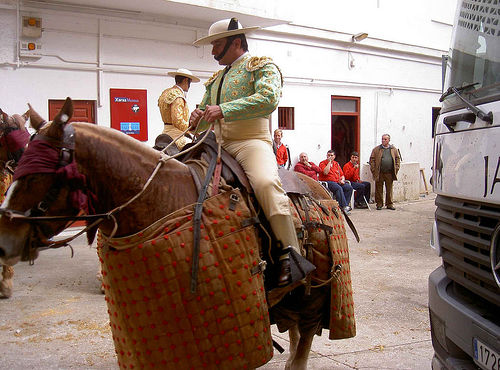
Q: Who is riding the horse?
A: A man.